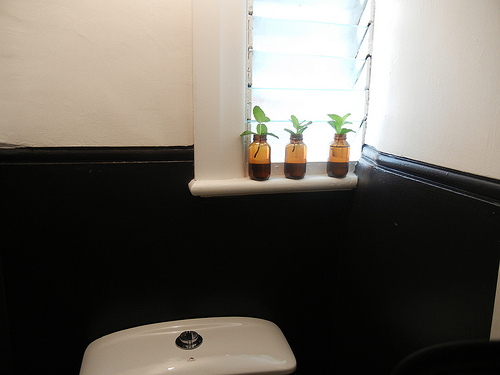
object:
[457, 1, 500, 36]
wall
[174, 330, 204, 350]
metal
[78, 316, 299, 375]
surface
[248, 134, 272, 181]
jar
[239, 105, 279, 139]
plant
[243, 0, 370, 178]
window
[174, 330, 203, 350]
toilet flush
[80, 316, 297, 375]
toilet tank lit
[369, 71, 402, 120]
right wall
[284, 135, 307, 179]
jar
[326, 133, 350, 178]
jar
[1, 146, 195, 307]
left wall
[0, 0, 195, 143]
left wall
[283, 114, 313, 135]
middle plant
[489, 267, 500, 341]
object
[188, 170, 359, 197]
window sill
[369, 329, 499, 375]
object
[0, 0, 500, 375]
bathroom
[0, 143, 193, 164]
moulding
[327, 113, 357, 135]
plants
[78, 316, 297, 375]
top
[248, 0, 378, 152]
sunlight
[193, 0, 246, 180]
moulding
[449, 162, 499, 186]
wall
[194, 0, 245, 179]
frame